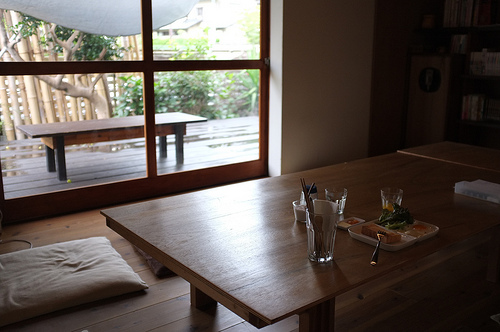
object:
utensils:
[300, 177, 314, 214]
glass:
[308, 216, 331, 254]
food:
[385, 232, 402, 245]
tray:
[343, 206, 443, 255]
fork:
[370, 230, 391, 266]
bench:
[16, 107, 207, 176]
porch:
[0, 114, 261, 200]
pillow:
[1, 234, 152, 327]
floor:
[0, 176, 291, 331]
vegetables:
[386, 218, 417, 231]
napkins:
[452, 178, 500, 207]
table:
[95, 138, 500, 332]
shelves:
[413, 22, 500, 39]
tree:
[0, 8, 137, 120]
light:
[200, 182, 273, 275]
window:
[0, 0, 146, 62]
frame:
[2, 0, 273, 222]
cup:
[304, 199, 342, 264]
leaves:
[161, 105, 173, 112]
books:
[468, 96, 480, 122]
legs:
[188, 283, 221, 317]